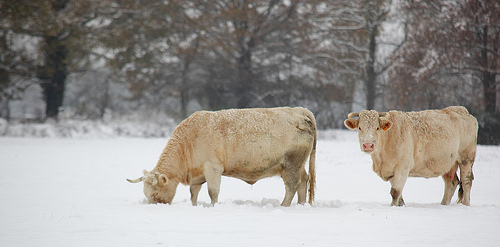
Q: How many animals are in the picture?
A: Two.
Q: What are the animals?
A: Bulls.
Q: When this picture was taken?
A: During the day.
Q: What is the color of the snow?
A: White.